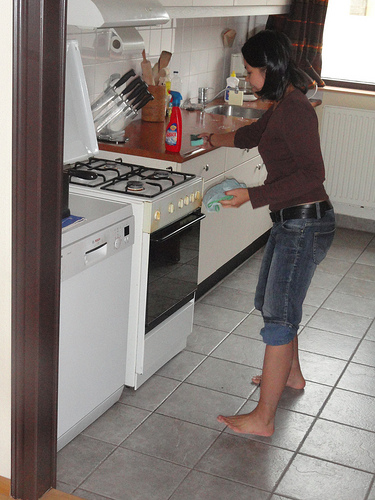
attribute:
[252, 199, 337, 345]
jeans — blue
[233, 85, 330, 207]
shirt — brown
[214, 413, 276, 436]
foot — bare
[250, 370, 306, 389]
foot — bare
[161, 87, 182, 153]
bottle — red, blue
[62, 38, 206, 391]
stove — white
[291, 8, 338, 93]
curtains — brown, orange, kitchen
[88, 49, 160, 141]
knives — set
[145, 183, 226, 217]
knobs — control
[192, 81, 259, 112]
faucet — chrome, kitchen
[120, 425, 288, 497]
tile — light colored, ceramic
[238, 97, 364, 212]
top — long sleeved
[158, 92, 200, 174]
bottle — spray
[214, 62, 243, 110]
soap — dishwashing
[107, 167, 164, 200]
burner — stove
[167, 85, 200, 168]
bottle — red, blue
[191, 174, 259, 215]
sponge — green, turquoise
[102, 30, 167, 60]
rack — paper towel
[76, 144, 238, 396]
oven — black, door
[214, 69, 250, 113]
bottle — clear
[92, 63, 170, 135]
knives — set, kitchen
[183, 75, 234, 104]
faucet — kitchen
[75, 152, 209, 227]
burners — four, stove top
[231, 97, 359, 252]
shirt — brown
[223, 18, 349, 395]
person — barefoot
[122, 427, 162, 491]
flooring — tile, section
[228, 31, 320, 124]
hair — black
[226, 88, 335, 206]
shirt — brown 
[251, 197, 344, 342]
jeans — rolled up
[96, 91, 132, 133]
holder — knife 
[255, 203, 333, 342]
jeans — Rolled up 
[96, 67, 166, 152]
utensils — Cooking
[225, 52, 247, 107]
maker — White coffee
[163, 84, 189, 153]
bottle — Cleaner 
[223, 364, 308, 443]
feet — bare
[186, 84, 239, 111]
sink faucet — stainless steel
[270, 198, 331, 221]
belt — black, leather